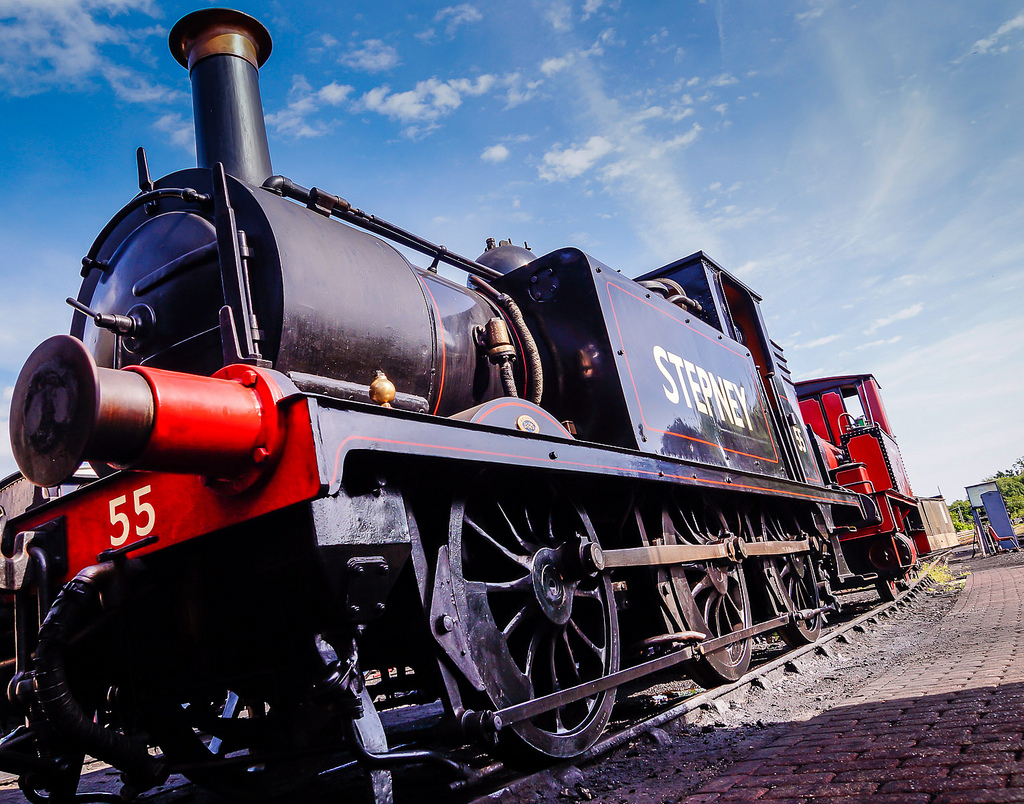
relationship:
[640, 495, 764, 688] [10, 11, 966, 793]
wheel on train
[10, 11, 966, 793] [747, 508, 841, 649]
train has wheel